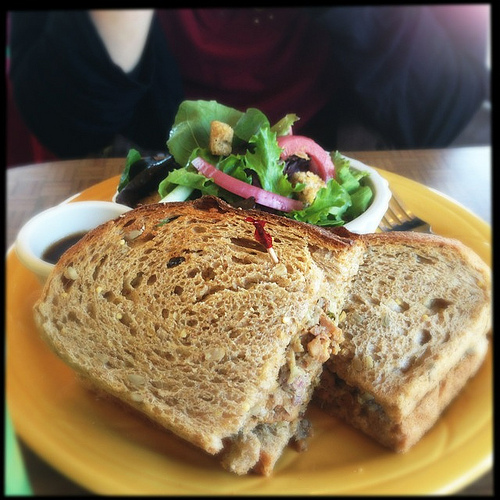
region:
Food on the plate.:
[80, 76, 418, 426]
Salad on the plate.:
[103, 111, 399, 207]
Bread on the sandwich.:
[19, 172, 468, 479]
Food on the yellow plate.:
[26, 170, 494, 450]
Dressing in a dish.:
[21, 185, 221, 325]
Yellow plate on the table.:
[12, 100, 252, 280]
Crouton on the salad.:
[152, 87, 235, 161]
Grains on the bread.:
[67, 247, 222, 354]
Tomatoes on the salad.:
[190, 122, 307, 206]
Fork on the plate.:
[338, 126, 449, 272]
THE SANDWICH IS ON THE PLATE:
[31, 192, 493, 479]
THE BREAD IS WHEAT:
[27, 191, 492, 473]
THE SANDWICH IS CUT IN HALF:
[32, 191, 494, 480]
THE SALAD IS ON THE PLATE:
[113, 89, 402, 251]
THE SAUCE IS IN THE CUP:
[11, 194, 147, 303]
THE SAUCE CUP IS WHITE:
[11, 195, 150, 294]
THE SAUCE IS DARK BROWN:
[34, 225, 95, 270]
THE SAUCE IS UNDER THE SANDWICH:
[20, 202, 145, 304]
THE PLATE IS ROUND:
[4, 156, 489, 494]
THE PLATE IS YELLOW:
[6, 156, 493, 493]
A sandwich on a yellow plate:
[23, 110, 493, 495]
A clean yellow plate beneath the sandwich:
[6, 379, 155, 481]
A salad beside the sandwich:
[115, 85, 390, 230]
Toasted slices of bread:
[79, 192, 321, 457]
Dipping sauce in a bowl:
[31, 197, 133, 278]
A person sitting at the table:
[10, 0, 482, 150]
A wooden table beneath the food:
[403, 150, 493, 217]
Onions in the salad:
[187, 129, 329, 217]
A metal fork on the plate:
[369, 180, 453, 258]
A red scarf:
[177, 17, 335, 130]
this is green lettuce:
[244, 119, 309, 213]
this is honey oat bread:
[48, 195, 340, 467]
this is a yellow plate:
[100, 430, 130, 466]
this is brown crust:
[122, 169, 379, 258]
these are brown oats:
[141, 278, 258, 367]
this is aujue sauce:
[15, 201, 170, 296]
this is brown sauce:
[43, 228, 72, 265]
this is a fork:
[341, 158, 464, 278]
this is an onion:
[198, 152, 323, 227]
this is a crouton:
[204, 112, 239, 164]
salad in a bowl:
[243, 118, 416, 231]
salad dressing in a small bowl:
[12, 204, 178, 255]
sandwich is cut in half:
[141, 199, 479, 409]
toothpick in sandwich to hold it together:
[234, 219, 351, 338]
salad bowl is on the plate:
[126, 110, 460, 233]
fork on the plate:
[346, 179, 472, 269]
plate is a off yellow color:
[168, 381, 419, 472]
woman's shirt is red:
[186, 18, 368, 116]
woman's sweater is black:
[18, 16, 132, 133]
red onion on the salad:
[182, 156, 310, 213]